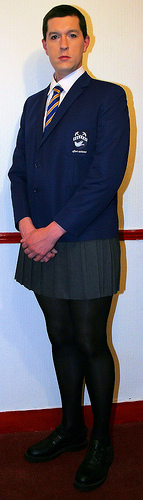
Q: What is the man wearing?
A: A kilt.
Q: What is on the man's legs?
A: Stockings.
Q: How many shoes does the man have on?
A: Two.